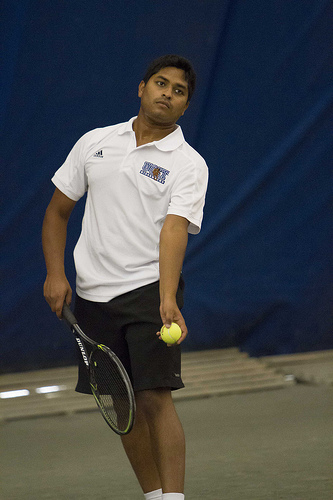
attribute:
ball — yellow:
[162, 325, 181, 342]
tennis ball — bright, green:
[159, 321, 181, 346]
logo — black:
[135, 159, 172, 185]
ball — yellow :
[160, 322, 180, 345]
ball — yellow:
[148, 309, 205, 347]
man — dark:
[39, 52, 208, 498]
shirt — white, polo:
[44, 114, 210, 302]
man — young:
[87, 51, 174, 257]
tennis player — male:
[80, 55, 222, 319]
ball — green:
[154, 314, 201, 352]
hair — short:
[142, 52, 197, 103]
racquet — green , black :
[43, 276, 167, 460]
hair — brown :
[140, 52, 201, 97]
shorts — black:
[72, 274, 185, 394]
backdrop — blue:
[3, 2, 322, 356]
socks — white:
[142, 488, 183, 498]